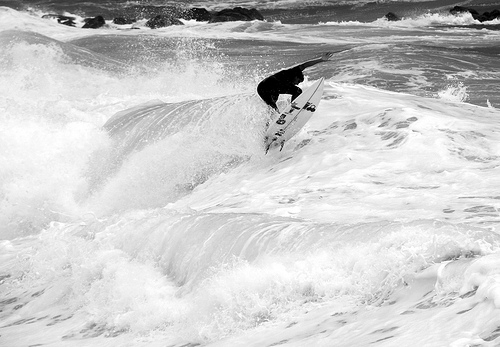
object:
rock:
[82, 12, 107, 24]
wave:
[86, 287, 176, 344]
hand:
[317, 51, 333, 62]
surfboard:
[264, 77, 329, 155]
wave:
[187, 203, 354, 301]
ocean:
[3, 3, 498, 333]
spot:
[168, 24, 489, 105]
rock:
[378, 11, 403, 23]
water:
[430, 203, 498, 345]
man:
[256, 47, 334, 110]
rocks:
[140, 12, 188, 34]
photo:
[3, 1, 498, 343]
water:
[136, 9, 226, 79]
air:
[393, 11, 396, 20]